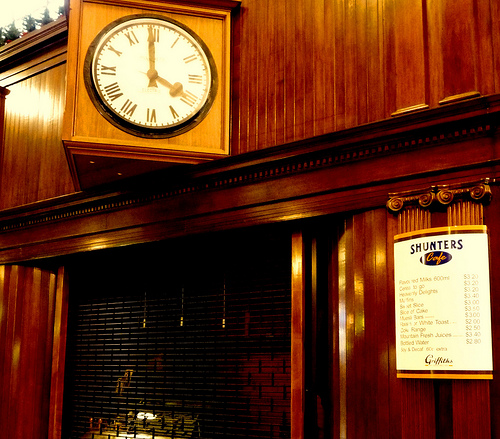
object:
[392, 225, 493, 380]
menu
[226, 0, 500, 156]
wall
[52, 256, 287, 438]
gate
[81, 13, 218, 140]
clock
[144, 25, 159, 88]
hand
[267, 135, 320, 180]
design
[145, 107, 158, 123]
number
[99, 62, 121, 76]
nine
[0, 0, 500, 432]
restaurant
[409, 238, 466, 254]
name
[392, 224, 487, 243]
line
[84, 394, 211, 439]
fireplace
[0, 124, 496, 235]
mantle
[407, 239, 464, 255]
word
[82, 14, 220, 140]
frame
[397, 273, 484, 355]
writing